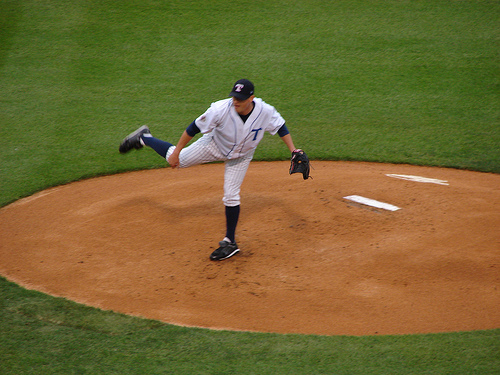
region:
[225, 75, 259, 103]
dark blue baseball cap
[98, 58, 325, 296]
the pitcher is pitching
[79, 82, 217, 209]
the pitcher has one foot off the ground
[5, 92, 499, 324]
the pitcher`s mound is round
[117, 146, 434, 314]
the dirt is light brown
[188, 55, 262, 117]
the player is wearing a hat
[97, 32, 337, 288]
the man is playing baseball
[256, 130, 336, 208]
the glove is black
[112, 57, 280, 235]
the uniform is white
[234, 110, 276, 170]
a blue T on the shirt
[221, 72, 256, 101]
the hat is dark blue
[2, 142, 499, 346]
the dirt is red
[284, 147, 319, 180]
the man is wearing a black glove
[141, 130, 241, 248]
the man is wearing black socks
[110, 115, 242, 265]
the man is wearing black shoes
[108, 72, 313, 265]
the man is standing on the pitchers mound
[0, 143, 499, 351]
the mound is round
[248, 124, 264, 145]
the man has a T on his shirt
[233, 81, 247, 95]
the man has a T on his hat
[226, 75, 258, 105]
the man's hat is black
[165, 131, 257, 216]
the man has pinstripes on his pants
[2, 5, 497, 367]
a scene happening during the day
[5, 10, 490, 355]
a scene outside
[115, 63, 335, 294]
a baseball pitcher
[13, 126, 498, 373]
a dirt mound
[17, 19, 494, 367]
a field of a baseball diamond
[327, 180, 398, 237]
a white plastic block on mound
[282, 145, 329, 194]
a glove on the person's hand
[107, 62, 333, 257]
a baseball player who is pitching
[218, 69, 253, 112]
a hat with the letter T on it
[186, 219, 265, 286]
a black shoe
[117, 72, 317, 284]
The pitcher stands on a pitcher's mound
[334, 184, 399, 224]
Dirt covers the plate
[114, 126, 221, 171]
The pitcher's right leg is in the air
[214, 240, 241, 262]
The pitcher wears black cleats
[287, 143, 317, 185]
The man has a glove on his hand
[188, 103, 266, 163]
The man is wearing a white jersey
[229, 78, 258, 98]
The man is wearing a black hat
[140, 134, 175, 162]
The pitcher's socks are blue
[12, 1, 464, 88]
Green grass grows on the field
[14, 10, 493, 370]
The man is playing baseball